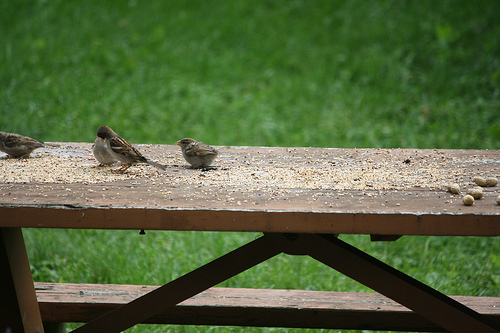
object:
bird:
[177, 138, 219, 171]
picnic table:
[0, 140, 500, 332]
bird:
[97, 125, 169, 174]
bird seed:
[0, 140, 500, 214]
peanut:
[448, 183, 460, 193]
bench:
[30, 281, 499, 331]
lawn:
[0, 0, 500, 333]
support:
[71, 232, 499, 333]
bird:
[92, 137, 120, 168]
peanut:
[468, 176, 499, 187]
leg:
[0, 227, 45, 332]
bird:
[0, 131, 52, 161]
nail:
[138, 229, 146, 235]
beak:
[176, 142, 184, 145]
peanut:
[460, 194, 474, 206]